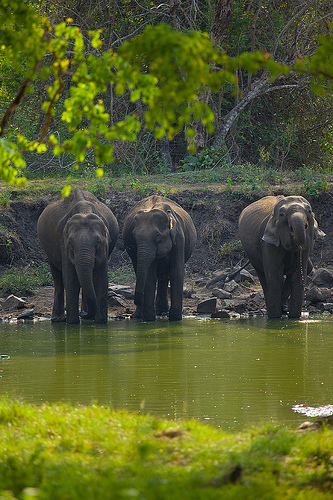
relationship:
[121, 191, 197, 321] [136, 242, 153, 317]
elephant has a trunk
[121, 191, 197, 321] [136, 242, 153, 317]
elephant owns a trunk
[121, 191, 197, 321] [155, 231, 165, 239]
elephant has an eye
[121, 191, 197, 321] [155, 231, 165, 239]
elephant owns an eye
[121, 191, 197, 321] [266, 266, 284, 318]
elephant has a leg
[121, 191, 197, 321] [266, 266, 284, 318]
elephant owns a leg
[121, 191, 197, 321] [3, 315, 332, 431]
elephant near water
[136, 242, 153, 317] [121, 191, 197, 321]
trunk on an elephant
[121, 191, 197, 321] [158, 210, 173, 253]
elephant has an ear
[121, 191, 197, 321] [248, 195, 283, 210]
elephant has a back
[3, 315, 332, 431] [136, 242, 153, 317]
water near trunk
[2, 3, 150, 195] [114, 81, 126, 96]
tree has leaves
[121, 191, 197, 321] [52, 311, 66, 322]
elephant has a foot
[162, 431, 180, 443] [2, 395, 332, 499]
mud in grass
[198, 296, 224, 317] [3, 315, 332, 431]
rock near water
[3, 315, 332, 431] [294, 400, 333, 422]
water has ripples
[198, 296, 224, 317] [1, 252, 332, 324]
rock on shore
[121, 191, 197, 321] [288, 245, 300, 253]
elephant has a mouth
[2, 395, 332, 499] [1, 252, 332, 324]
grass on shore